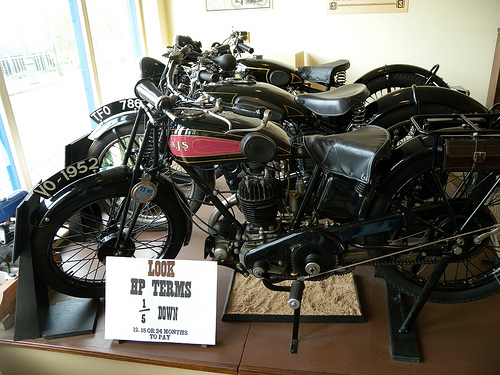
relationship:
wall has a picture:
[166, 3, 499, 114] [330, 0, 407, 17]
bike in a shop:
[34, 45, 499, 305] [1, 1, 498, 372]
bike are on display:
[31, 44, 500, 354] [17, 27, 495, 358]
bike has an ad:
[34, 45, 499, 305] [104, 254, 219, 346]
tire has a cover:
[30, 183, 184, 300] [27, 166, 194, 247]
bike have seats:
[31, 44, 500, 354] [301, 123, 392, 187]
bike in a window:
[31, 44, 500, 354] [3, 4, 108, 184]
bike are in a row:
[31, 44, 500, 354] [245, 58, 360, 354]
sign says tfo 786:
[105, 255, 216, 345] [89, 99, 145, 124]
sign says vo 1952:
[105, 255, 216, 345] [33, 157, 101, 197]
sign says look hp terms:
[105, 255, 216, 345] [129, 261, 192, 298]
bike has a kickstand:
[31, 44, 500, 354] [291, 301, 301, 352]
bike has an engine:
[31, 44, 500, 354] [237, 174, 282, 229]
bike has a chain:
[31, 44, 500, 354] [266, 259, 480, 282]